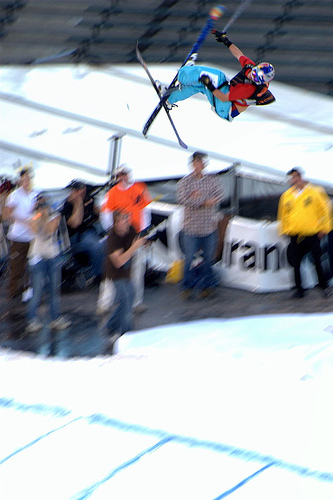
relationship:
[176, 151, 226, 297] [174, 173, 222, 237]
man wearing shirt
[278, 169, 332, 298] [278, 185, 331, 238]
man wearing jacket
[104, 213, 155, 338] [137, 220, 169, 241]
man holding camera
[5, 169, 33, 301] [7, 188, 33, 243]
man wearing shirt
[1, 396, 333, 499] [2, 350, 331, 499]
lines in snow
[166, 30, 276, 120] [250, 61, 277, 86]
man wearing helmet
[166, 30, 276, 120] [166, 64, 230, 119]
man wearing pants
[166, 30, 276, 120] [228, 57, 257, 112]
man wearing shirt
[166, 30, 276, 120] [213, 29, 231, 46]
man wearing glove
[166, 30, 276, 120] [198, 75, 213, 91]
man wearing glove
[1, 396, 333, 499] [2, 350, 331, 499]
lines on snow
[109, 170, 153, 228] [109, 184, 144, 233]
man wearing shirt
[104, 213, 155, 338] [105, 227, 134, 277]
man wearing shirt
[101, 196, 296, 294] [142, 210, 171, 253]
sign with logo